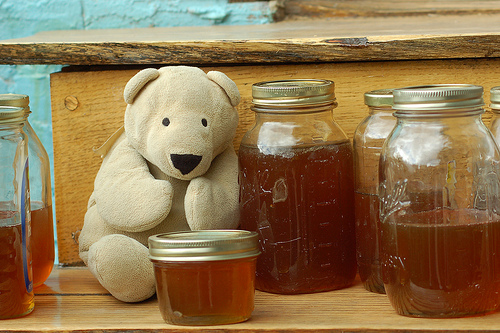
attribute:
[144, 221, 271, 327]
jar — smaller, sitting, small, full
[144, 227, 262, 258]
lid — goldtone, silver, metal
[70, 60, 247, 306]
teddy bear — leaning, tan, toy, stuffed, white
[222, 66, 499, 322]
jars — large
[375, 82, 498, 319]
jar — half full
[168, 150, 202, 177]
nose — black, sewn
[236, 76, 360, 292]
jar — full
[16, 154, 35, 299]
label — bordered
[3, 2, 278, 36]
wall — aqua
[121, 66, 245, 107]
ears — annular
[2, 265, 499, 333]
shelf — wooden